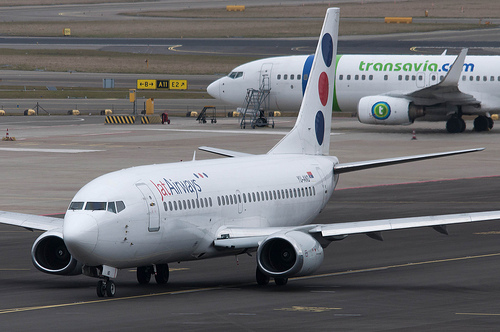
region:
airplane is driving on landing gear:
[1, 6, 499, 296]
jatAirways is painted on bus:
[148, 173, 202, 202]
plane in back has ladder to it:
[206, 46, 498, 131]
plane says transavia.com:
[354, 60, 476, 73]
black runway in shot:
[0, 176, 499, 329]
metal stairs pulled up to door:
[235, 85, 272, 130]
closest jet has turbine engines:
[31, 225, 326, 282]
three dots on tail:
[313, 33, 335, 150]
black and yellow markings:
[136, 77, 189, 89]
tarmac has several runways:
[3, 2, 498, 115]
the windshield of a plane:
[66, 197, 129, 217]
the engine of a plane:
[26, 222, 81, 278]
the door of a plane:
[133, 179, 168, 237]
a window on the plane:
[159, 198, 171, 213]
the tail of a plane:
[194, 7, 486, 175]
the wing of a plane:
[211, 205, 498, 281]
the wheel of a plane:
[92, 275, 119, 297]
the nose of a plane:
[58, 210, 100, 255]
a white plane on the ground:
[0, 5, 499, 303]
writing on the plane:
[147, 174, 206, 204]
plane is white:
[70, 20, 412, 289]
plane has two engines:
[5, 179, 350, 321]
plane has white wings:
[6, 118, 498, 257]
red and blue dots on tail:
[294, 22, 340, 145]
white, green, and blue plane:
[239, 47, 499, 110]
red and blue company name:
[135, 141, 237, 209]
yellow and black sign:
[128, 60, 197, 89]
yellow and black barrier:
[103, 98, 163, 135]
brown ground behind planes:
[28, 2, 335, 74]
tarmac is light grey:
[20, 98, 202, 205]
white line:
[21, 268, 91, 318]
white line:
[30, 278, 65, 312]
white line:
[21, 281, 73, 326]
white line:
[31, 288, 88, 313]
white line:
[44, 290, 132, 328]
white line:
[52, 287, 82, 308]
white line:
[35, 282, 95, 327]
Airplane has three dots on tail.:
[66, 5, 436, 286]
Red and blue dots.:
[285, 5, 376, 259]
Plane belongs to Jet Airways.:
[5, 3, 499, 303]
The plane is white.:
[8, 3, 497, 317]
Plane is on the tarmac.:
[2, 2, 499, 329]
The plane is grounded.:
[0, 5, 499, 319]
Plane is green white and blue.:
[201, 30, 498, 144]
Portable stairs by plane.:
[188, 20, 495, 162]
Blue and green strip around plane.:
[183, 23, 494, 138]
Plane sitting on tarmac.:
[201, 50, 498, 154]